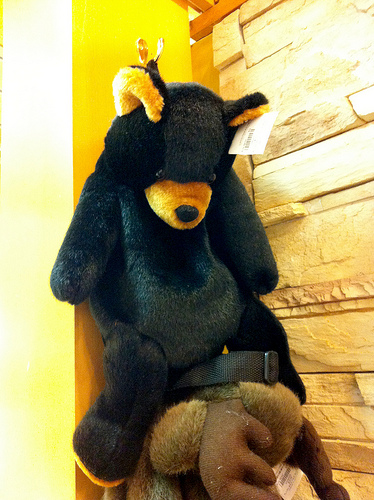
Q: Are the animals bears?
A: No, they are mooses and bears.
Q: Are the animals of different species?
A: Yes, they are mooses and bears.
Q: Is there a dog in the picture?
A: No, there are no dogs.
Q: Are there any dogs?
A: No, there are no dogs.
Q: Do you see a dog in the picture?
A: No, there are no dogs.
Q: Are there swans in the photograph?
A: No, there are no swans.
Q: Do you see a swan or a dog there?
A: No, there are no swans or dogs.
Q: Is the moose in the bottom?
A: Yes, the moose is in the bottom of the image.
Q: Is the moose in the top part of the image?
A: No, the moose is in the bottom of the image.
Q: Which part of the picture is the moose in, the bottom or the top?
A: The moose is in the bottom of the image.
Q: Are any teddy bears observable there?
A: Yes, there is a teddy bear.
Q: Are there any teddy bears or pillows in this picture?
A: Yes, there is a teddy bear.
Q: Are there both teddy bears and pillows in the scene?
A: No, there is a teddy bear but no pillows.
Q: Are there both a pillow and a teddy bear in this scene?
A: No, there is a teddy bear but no pillows.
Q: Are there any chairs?
A: No, there are no chairs.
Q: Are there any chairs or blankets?
A: No, there are no chairs or blankets.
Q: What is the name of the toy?
A: The toy is a teddy bear.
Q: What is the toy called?
A: The toy is a teddy bear.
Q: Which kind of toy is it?
A: The toy is a teddy bear.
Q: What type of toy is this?
A: This is a teddy bear.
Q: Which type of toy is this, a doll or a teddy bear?
A: This is a teddy bear.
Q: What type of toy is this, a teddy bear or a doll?
A: This is a teddy bear.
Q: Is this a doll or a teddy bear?
A: This is a teddy bear.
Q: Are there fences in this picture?
A: No, there are no fences.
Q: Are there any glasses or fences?
A: No, there are no fences or glasses.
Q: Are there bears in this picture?
A: Yes, there is a bear.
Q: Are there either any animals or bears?
A: Yes, there is a bear.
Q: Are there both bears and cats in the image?
A: No, there is a bear but no cats.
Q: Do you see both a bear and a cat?
A: No, there is a bear but no cats.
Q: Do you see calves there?
A: No, there are no calves.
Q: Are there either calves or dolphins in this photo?
A: No, there are no calves or dolphins.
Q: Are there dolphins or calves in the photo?
A: No, there are no calves or dolphins.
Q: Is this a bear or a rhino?
A: This is a bear.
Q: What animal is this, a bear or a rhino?
A: This is a bear.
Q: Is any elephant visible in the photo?
A: No, there are no elephants.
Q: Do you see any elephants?
A: No, there are no elephants.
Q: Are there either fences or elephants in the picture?
A: No, there are no elephants or fences.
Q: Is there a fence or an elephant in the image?
A: No, there are no elephants or fences.